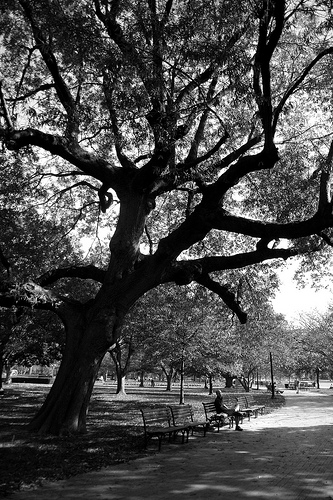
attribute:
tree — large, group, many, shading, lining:
[71, 85, 316, 292]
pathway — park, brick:
[76, 369, 318, 500]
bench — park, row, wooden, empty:
[121, 391, 215, 457]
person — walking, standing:
[278, 351, 314, 399]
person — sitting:
[196, 380, 248, 434]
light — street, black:
[249, 324, 279, 394]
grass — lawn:
[107, 391, 144, 449]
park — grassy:
[5, 330, 287, 469]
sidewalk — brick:
[217, 388, 318, 494]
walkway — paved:
[166, 424, 295, 498]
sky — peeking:
[301, 279, 318, 294]